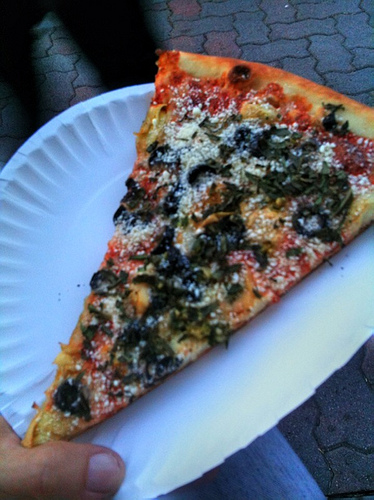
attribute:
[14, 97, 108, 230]
plate — paper, white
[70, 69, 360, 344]
pizza — sliced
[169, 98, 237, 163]
cheese — white, grated, parmesan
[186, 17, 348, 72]
ground — brick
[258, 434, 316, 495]
jeans — blue, wooden, denim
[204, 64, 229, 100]
sauce — red, tomato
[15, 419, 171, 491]
thumb — white, holding, short, caucasian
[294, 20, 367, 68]
brick — paved, cracked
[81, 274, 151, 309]
olive — black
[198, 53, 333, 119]
crust — bubbled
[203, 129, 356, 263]
herbs — green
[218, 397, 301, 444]
edge — scalloped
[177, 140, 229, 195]
parmesan — ground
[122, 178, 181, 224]
olives — black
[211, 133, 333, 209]
spinach — green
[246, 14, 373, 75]
bricks — pink